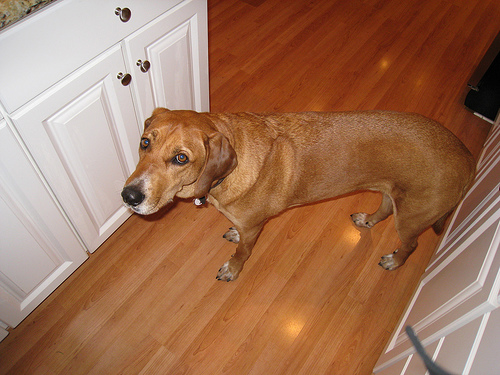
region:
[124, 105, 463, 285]
A brown dog standing between the cabinets.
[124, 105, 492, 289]
A brown dog with a black nose.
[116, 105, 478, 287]
A brown dog with orange and blue eyes.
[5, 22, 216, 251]
A white cabinet in front of the dog.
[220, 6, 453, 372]
A wooden floor that the dog is stepping on.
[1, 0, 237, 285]
Cabinet painted white in color.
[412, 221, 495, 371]
Cabinet painted white in color.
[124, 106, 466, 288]
A dog with its ears fallen on the sides.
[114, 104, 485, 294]
A dog standing in the kitchen.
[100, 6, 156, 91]
Knobs of the white cabinet.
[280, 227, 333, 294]
part of a floor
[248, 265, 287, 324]
part of a board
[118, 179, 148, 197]
nose of a dog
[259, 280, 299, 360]
part of a light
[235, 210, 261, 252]
part of a leg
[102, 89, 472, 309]
dog standing on wood floor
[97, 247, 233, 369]
tan panels of wood floor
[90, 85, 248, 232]
dog next to a white cabinet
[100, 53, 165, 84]
silver knobs on white cabinet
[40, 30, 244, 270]
white cabinet doors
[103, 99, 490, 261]
dog with brown fur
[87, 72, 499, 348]
dog standing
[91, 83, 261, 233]
dog looking at camera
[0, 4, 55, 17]
granite countertop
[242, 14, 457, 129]
reflections of light on wood floor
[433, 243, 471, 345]
The cabinets are white.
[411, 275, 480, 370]
The cabinets are white.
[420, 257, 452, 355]
The cabinets are white.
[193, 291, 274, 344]
The floor is wooden.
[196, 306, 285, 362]
The floor is wooden.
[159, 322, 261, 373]
The floor is wooden.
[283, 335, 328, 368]
The floor is wooden.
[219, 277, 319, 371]
The floor is wooden.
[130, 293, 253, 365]
The floor is wooden.